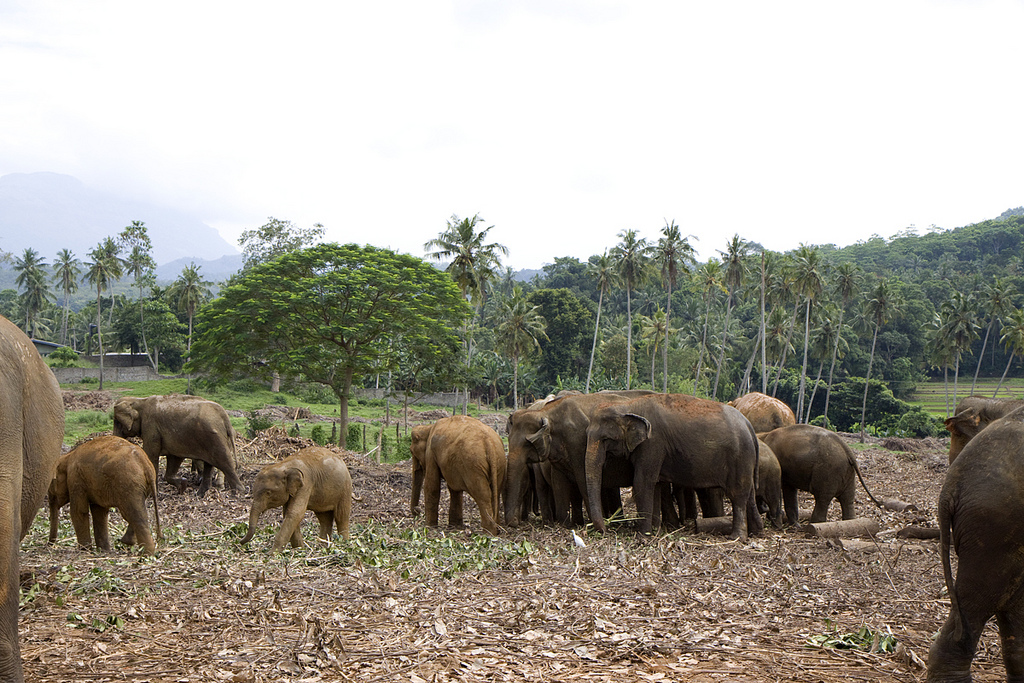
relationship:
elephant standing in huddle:
[577, 385, 768, 539] [407, 383, 883, 531]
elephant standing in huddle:
[500, 390, 572, 525] [407, 383, 883, 531]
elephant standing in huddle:
[521, 387, 602, 522] [407, 383, 883, 531]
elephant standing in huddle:
[750, 418, 885, 520] [407, 383, 883, 531]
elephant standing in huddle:
[750, 433, 792, 527] [407, 383, 883, 531]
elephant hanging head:
[44, 431, 166, 563] [42, 448, 73, 507]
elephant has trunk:
[543, 389, 656, 537] [576, 436, 618, 532]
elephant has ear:
[505, 380, 653, 532] [619, 402, 659, 448]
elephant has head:
[237, 430, 365, 560] [237, 449, 305, 514]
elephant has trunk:
[526, 380, 654, 528] [580, 422, 613, 528]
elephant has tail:
[399, 402, 523, 547] [479, 432, 510, 513]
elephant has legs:
[237, 436, 361, 551] [269, 488, 311, 560]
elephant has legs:
[399, 402, 514, 541] [474, 482, 514, 532]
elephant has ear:
[237, 436, 361, 551] [269, 450, 302, 487]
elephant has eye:
[548, 376, 655, 519] [600, 408, 618, 430]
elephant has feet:
[42, 422, 179, 552] [68, 504, 161, 556]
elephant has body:
[107, 383, 246, 500] [135, 398, 241, 463]